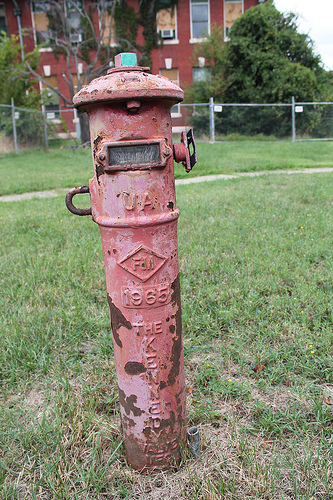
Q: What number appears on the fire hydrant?
A: 1965.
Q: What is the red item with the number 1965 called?
A: Fire hydrant.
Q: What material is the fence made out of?
A: Metal.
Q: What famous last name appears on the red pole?
A: Kennedy.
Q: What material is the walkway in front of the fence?
A: Concrete.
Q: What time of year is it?
A: Summer.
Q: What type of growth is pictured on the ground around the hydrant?
A: Grass.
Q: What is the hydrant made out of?
A: Metal.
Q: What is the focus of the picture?
A: Fire hydrant.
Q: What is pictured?
A: A fire hydrant.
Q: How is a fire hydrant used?
A: To put out fires.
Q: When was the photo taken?
A: Daytime.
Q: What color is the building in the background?
A: Red.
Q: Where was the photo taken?
A: Near a fire hydrant.